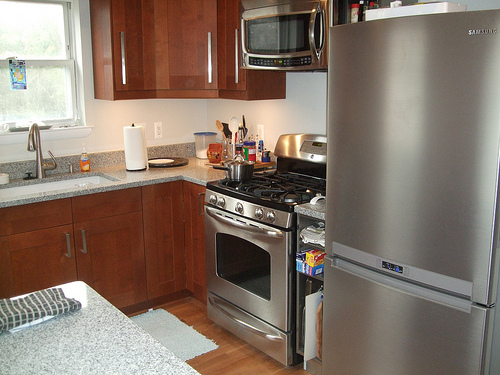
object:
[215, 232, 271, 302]
window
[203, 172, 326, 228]
burner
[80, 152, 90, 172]
bottle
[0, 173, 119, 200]
sink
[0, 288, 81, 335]
towel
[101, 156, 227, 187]
counter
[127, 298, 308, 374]
floor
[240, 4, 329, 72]
microwave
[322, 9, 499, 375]
refrigerator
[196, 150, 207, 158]
substance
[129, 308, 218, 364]
rug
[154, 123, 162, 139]
wall outlet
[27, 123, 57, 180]
sink faucet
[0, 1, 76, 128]
kitchen window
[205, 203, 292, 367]
oven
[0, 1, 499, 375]
kitchen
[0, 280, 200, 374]
counter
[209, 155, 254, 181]
pot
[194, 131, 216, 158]
canister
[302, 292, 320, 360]
cutting board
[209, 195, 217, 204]
knob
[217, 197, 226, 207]
knob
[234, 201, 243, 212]
knob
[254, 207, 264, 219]
knob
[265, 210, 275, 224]
knob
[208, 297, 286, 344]
handle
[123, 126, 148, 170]
paper towel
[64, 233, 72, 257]
handle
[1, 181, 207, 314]
cabinet